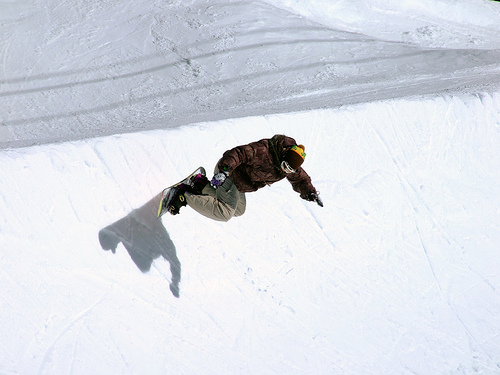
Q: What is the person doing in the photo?
A: Snowboarding.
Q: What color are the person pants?
A: Khaki.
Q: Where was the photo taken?
A: On the slopes.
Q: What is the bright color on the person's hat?
A: Yellow.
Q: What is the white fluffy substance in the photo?
A: Snow.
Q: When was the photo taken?
A: Winter.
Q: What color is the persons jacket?
A: Brown.